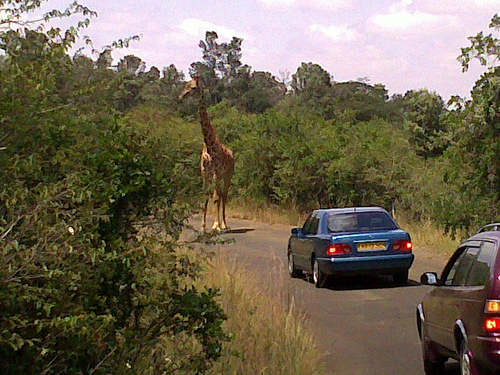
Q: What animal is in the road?
A: A giraffe.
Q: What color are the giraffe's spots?
A: Brown.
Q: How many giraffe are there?
A: 1.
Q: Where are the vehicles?
A: On the road.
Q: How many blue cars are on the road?
A: 1.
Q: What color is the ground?
A: Gray.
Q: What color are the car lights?
A: Red.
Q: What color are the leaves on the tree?
A: Green.